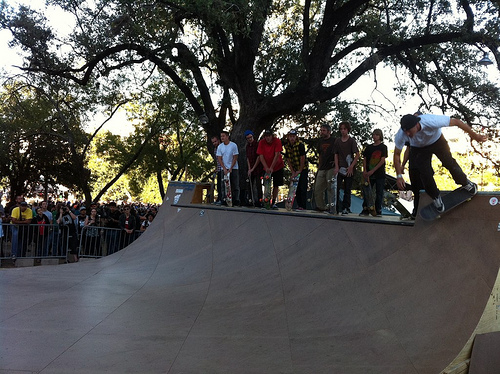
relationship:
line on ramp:
[81, 282, 152, 324] [63, 233, 465, 350]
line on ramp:
[176, 264, 226, 330] [63, 233, 465, 350]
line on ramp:
[264, 225, 298, 319] [63, 233, 465, 350]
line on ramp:
[335, 225, 378, 290] [63, 233, 465, 350]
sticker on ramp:
[174, 186, 184, 195] [63, 233, 465, 350]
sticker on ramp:
[171, 192, 182, 204] [63, 233, 465, 350]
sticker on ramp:
[197, 209, 207, 217] [63, 233, 465, 350]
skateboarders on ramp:
[197, 123, 460, 215] [63, 233, 465, 350]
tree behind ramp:
[7, 1, 483, 216] [6, 190, 484, 369]